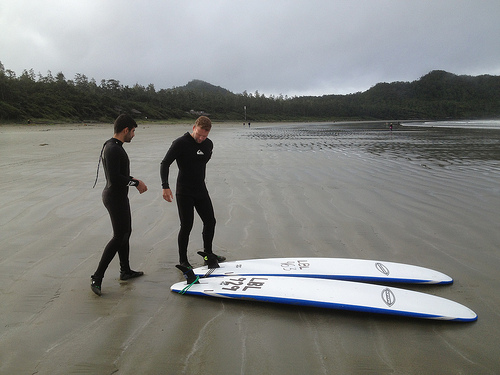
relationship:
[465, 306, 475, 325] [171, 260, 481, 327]
tip of surfboard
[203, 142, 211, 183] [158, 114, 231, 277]
arm of man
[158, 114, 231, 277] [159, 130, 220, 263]
man in wetsuit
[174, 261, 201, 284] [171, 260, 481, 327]
fin on surfboard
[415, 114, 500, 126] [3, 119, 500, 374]
wave on beach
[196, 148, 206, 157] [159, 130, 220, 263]
logo on wetsuit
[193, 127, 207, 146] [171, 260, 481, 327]
face looking at surfboard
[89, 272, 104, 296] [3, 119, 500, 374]
foot on beach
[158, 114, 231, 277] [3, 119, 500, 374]
man on beach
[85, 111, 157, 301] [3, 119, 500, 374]
man on beach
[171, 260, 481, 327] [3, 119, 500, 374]
surfboard on beach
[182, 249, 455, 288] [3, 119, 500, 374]
surfboard on beach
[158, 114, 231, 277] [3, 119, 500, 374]
man in beach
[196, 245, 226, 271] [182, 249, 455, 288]
fin on surfboard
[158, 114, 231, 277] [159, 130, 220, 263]
man wearing wetsuit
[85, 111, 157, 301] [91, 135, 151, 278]
man wearing wetsuit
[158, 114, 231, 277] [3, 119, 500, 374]
man at beach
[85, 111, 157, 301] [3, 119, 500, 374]
man at beach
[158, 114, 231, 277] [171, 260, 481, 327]
man checking surfboard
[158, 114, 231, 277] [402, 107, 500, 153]
man close to ocean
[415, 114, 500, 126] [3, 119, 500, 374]
wave of beach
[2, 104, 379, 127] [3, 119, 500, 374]
bank on beach